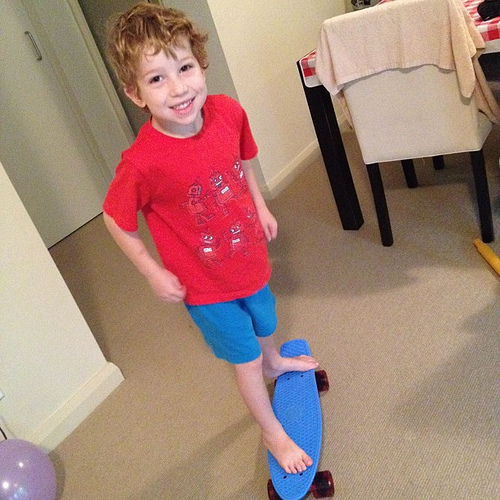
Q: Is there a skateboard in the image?
A: Yes, there is a skateboard.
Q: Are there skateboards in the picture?
A: Yes, there is a skateboard.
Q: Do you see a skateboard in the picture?
A: Yes, there is a skateboard.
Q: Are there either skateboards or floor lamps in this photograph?
A: Yes, there is a skateboard.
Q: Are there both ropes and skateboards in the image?
A: No, there is a skateboard but no ropes.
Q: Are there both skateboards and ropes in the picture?
A: No, there is a skateboard but no ropes.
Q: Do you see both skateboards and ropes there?
A: No, there is a skateboard but no ropes.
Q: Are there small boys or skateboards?
A: Yes, there is a small skateboard.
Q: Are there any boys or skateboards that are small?
A: Yes, the skateboard is small.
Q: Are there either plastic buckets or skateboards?
A: Yes, there is a plastic skateboard.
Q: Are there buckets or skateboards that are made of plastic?
A: Yes, the skateboard is made of plastic.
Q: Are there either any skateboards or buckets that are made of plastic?
A: Yes, the skateboard is made of plastic.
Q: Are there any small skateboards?
A: Yes, there is a small skateboard.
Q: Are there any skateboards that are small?
A: Yes, there is a skateboard that is small.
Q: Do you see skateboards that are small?
A: Yes, there is a skateboard that is small.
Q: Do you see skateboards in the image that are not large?
A: Yes, there is a small skateboard.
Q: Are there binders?
A: No, there are no binders.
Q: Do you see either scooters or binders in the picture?
A: No, there are no binders or scooters.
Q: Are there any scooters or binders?
A: No, there are no binders or scooters.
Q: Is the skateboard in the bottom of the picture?
A: Yes, the skateboard is in the bottom of the image.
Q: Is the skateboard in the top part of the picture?
A: No, the skateboard is in the bottom of the image.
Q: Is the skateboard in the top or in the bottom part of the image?
A: The skateboard is in the bottom of the image.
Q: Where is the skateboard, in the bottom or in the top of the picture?
A: The skateboard is in the bottom of the image.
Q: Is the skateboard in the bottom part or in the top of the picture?
A: The skateboard is in the bottom of the image.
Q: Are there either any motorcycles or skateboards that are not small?
A: No, there is a skateboard but it is small.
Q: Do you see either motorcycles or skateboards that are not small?
A: No, there is a skateboard but it is small.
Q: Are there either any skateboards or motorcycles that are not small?
A: No, there is a skateboard but it is small.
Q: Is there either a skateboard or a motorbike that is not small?
A: No, there is a skateboard but it is small.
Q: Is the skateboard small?
A: Yes, the skateboard is small.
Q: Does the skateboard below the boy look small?
A: Yes, the skateboard is small.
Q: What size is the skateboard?
A: The skateboard is small.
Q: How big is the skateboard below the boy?
A: The skateboard is small.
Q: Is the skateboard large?
A: No, the skateboard is small.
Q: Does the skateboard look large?
A: No, the skateboard is small.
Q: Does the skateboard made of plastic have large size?
A: No, the skateboard is small.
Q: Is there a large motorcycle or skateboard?
A: No, there is a skateboard but it is small.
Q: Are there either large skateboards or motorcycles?
A: No, there is a skateboard but it is small.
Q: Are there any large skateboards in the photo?
A: No, there is a skateboard but it is small.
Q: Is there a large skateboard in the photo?
A: No, there is a skateboard but it is small.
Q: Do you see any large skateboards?
A: No, there is a skateboard but it is small.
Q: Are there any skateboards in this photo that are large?
A: No, there is a skateboard but it is small.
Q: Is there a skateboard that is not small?
A: No, there is a skateboard but it is small.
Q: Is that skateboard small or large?
A: The skateboard is small.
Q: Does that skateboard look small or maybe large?
A: The skateboard is small.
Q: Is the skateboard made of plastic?
A: Yes, the skateboard is made of plastic.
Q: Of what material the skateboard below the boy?
A: The skateboard is made of plastic.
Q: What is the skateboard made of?
A: The skateboard is made of plastic.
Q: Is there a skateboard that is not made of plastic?
A: No, there is a skateboard but it is made of plastic.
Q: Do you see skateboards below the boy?
A: Yes, there is a skateboard below the boy.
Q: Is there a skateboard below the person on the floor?
A: Yes, there is a skateboard below the boy.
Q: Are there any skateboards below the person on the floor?
A: Yes, there is a skateboard below the boy.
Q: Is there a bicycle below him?
A: No, there is a skateboard below the boy.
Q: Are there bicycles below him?
A: No, there is a skateboard below the boy.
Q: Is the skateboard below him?
A: Yes, the skateboard is below the boy.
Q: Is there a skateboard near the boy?
A: Yes, there is a skateboard near the boy.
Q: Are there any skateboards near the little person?
A: Yes, there is a skateboard near the boy.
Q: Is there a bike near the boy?
A: No, there is a skateboard near the boy.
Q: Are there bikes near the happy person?
A: No, there is a skateboard near the boy.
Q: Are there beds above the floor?
A: No, there is a skateboard above the floor.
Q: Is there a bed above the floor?
A: No, there is a skateboard above the floor.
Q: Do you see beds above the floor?
A: No, there is a skateboard above the floor.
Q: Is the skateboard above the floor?
A: Yes, the skateboard is above the floor.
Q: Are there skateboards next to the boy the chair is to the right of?
A: Yes, there is a skateboard next to the boy.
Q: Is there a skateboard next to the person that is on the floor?
A: Yes, there is a skateboard next to the boy.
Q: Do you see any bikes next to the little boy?
A: No, there is a skateboard next to the boy.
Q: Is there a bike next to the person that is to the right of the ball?
A: No, there is a skateboard next to the boy.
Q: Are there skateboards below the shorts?
A: Yes, there is a skateboard below the shorts.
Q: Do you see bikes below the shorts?
A: No, there is a skateboard below the shorts.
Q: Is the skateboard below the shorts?
A: Yes, the skateboard is below the shorts.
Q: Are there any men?
A: No, there are no men.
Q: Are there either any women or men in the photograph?
A: No, there are no men or women.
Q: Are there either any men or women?
A: No, there are no men or women.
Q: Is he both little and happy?
A: Yes, the boy is little and happy.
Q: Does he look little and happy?
A: Yes, the boy is little and happy.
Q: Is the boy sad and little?
A: No, the boy is little but happy.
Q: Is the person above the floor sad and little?
A: No, the boy is little but happy.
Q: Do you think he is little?
A: Yes, the boy is little.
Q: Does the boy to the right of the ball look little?
A: Yes, the boy is little.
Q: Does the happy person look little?
A: Yes, the boy is little.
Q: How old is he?
A: The boy is little.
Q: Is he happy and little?
A: Yes, the boy is happy and little.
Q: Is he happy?
A: Yes, the boy is happy.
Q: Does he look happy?
A: Yes, the boy is happy.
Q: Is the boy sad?
A: No, the boy is happy.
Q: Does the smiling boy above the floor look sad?
A: No, the boy is happy.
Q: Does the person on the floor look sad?
A: No, the boy is happy.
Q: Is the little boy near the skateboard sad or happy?
A: The boy is happy.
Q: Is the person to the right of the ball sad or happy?
A: The boy is happy.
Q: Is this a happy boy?
A: Yes, this is a happy boy.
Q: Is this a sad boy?
A: No, this is a happy boy.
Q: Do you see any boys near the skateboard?
A: Yes, there is a boy near the skateboard.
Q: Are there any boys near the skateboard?
A: Yes, there is a boy near the skateboard.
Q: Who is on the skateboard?
A: The boy is on the skateboard.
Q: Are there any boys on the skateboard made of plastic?
A: Yes, there is a boy on the skateboard.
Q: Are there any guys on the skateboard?
A: No, there is a boy on the skateboard.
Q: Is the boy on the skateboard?
A: Yes, the boy is on the skateboard.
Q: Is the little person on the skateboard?
A: Yes, the boy is on the skateboard.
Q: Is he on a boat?
A: No, the boy is on the skateboard.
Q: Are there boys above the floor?
A: Yes, there is a boy above the floor.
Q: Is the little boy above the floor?
A: Yes, the boy is above the floor.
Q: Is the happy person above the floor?
A: Yes, the boy is above the floor.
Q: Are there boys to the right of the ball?
A: Yes, there is a boy to the right of the ball.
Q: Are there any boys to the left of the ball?
A: No, the boy is to the right of the ball.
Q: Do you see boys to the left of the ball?
A: No, the boy is to the right of the ball.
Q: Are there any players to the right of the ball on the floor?
A: No, there is a boy to the right of the ball.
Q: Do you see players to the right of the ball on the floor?
A: No, there is a boy to the right of the ball.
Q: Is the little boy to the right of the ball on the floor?
A: Yes, the boy is to the right of the ball.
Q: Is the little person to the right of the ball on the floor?
A: Yes, the boy is to the right of the ball.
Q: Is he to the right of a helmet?
A: No, the boy is to the right of the ball.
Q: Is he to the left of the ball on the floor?
A: No, the boy is to the right of the ball.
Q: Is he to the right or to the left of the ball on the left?
A: The boy is to the right of the ball.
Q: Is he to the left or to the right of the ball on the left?
A: The boy is to the right of the ball.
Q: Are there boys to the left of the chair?
A: Yes, there is a boy to the left of the chair.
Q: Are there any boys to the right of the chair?
A: No, the boy is to the left of the chair.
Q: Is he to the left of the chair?
A: Yes, the boy is to the left of the chair.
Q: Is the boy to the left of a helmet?
A: No, the boy is to the left of the chair.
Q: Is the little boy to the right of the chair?
A: No, the boy is to the left of the chair.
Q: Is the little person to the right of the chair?
A: No, the boy is to the left of the chair.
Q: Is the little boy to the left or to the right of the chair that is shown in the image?
A: The boy is to the left of the chair.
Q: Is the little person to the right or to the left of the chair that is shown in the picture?
A: The boy is to the left of the chair.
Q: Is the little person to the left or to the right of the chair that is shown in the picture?
A: The boy is to the left of the chair.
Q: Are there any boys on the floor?
A: Yes, there is a boy on the floor.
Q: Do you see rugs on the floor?
A: No, there is a boy on the floor.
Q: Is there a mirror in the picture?
A: No, there are no mirrors.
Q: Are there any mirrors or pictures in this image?
A: No, there are no mirrors or pictures.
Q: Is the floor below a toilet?
A: No, the floor is below the ball.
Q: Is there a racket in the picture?
A: No, there are no rackets.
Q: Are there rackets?
A: No, there are no rackets.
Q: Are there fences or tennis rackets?
A: No, there are no tennis rackets or fences.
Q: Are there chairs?
A: Yes, there is a chair.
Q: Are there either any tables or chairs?
A: Yes, there is a chair.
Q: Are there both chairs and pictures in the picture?
A: No, there is a chair but no pictures.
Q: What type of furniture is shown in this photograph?
A: The furniture is a chair.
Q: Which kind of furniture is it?
A: The piece of furniture is a chair.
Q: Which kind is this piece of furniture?
A: This is a chair.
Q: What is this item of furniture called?
A: This is a chair.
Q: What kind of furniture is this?
A: This is a chair.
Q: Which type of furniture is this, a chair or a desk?
A: This is a chair.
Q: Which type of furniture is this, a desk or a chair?
A: This is a chair.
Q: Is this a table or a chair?
A: This is a chair.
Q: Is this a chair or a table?
A: This is a chair.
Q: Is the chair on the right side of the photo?
A: Yes, the chair is on the right of the image.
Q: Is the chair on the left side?
A: No, the chair is on the right of the image.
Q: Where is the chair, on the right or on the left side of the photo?
A: The chair is on the right of the image.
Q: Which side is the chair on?
A: The chair is on the right of the image.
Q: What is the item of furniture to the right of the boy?
A: The piece of furniture is a chair.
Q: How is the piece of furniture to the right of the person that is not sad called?
A: The piece of furniture is a chair.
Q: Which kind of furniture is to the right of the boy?
A: The piece of furniture is a chair.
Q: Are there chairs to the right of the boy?
A: Yes, there is a chair to the right of the boy.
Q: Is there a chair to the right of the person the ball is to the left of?
A: Yes, there is a chair to the right of the boy.